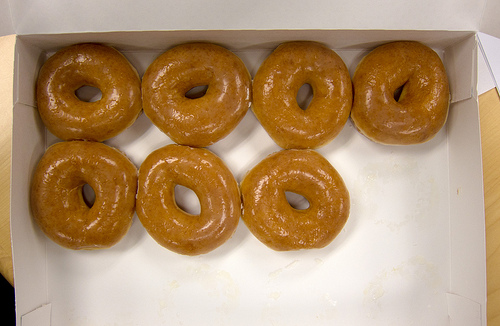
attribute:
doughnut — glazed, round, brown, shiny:
[35, 41, 142, 140]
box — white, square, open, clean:
[0, 0, 500, 325]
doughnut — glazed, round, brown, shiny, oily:
[145, 40, 249, 146]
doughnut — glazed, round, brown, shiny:
[31, 143, 135, 249]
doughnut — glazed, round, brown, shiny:
[135, 147, 241, 253]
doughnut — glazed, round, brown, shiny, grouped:
[250, 40, 357, 152]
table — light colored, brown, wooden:
[1, 35, 500, 324]